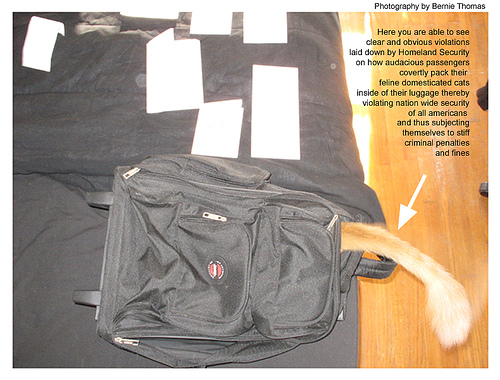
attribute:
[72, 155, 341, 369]
suitcase — black, dark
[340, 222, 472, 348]
tail — fluffy, animals, cats, orange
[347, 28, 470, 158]
text — warning, black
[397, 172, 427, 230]
arrow — white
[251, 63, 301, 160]
envelope — white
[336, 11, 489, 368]
floor — wood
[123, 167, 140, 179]
zipper — metal, silver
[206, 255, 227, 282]
logo — red, black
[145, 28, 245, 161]
papers — white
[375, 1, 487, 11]
credit — black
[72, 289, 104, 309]
foot — black